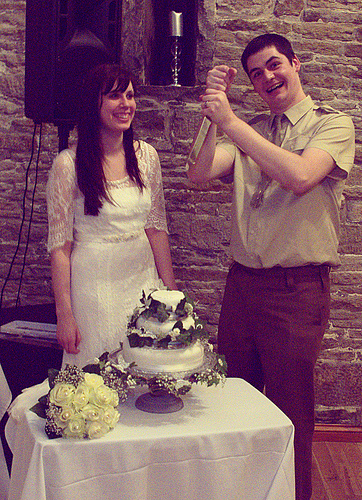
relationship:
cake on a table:
[126, 286, 205, 377] [17, 375, 300, 499]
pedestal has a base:
[137, 380, 184, 416] [135, 393, 185, 414]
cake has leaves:
[126, 286, 205, 377] [206, 354, 229, 389]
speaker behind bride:
[24, 3, 119, 123] [45, 65, 176, 376]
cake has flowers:
[126, 286, 205, 377] [183, 317, 195, 331]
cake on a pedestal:
[126, 286, 205, 377] [137, 380, 184, 416]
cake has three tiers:
[126, 286, 205, 377] [122, 289, 208, 373]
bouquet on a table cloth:
[41, 366, 118, 436] [5, 375, 299, 499]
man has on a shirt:
[187, 36, 354, 499] [229, 96, 357, 269]